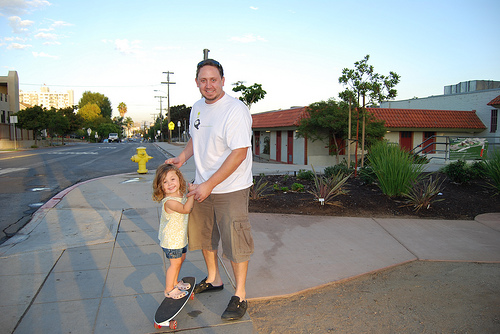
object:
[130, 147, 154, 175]
fire hydrant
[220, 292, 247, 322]
shoes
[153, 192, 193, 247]
shirt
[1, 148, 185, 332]
sidewalk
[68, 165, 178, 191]
curb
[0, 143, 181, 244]
road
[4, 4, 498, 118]
sky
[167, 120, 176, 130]
sign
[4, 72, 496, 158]
background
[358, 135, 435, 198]
plants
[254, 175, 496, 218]
dirt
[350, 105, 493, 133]
roof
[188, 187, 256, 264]
shorts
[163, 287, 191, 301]
shoes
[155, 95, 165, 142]
poles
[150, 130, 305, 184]
sidewalk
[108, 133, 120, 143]
car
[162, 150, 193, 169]
corner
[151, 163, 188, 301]
girl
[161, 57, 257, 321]
man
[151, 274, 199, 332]
skateboard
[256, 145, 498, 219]
landscaping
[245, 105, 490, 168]
building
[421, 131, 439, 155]
doors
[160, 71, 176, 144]
pole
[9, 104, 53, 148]
trees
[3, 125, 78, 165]
sidewalk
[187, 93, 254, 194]
shirt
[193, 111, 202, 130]
graphic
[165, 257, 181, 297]
leg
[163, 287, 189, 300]
feet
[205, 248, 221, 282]
leg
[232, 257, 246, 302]
leg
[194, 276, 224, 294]
feet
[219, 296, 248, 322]
feet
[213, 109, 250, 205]
arm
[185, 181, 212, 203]
hand